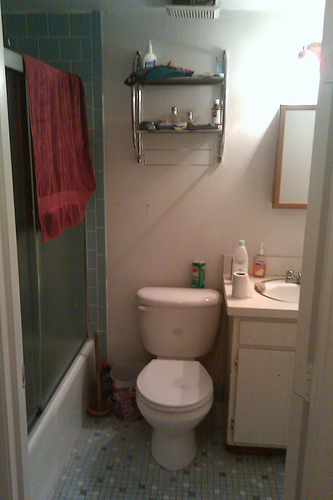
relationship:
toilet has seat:
[134, 285, 223, 471] [135, 356, 213, 414]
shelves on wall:
[137, 55, 225, 162] [164, 32, 239, 48]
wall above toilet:
[164, 32, 239, 48] [141, 291, 212, 466]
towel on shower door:
[13, 52, 96, 240] [4, 47, 88, 434]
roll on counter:
[230, 271, 250, 300] [218, 253, 304, 318]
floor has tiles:
[59, 463, 282, 498] [62, 476, 114, 498]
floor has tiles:
[59, 463, 282, 498] [164, 479, 281, 498]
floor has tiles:
[59, 463, 282, 498] [200, 449, 279, 488]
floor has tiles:
[59, 463, 282, 498] [82, 421, 143, 470]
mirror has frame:
[272, 103, 316, 209] [272, 97, 287, 207]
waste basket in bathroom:
[112, 372, 143, 433] [0, 1, 332, 498]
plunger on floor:
[81, 328, 121, 425] [44, 390, 284, 495]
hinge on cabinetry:
[230, 414, 236, 432] [223, 314, 293, 452]